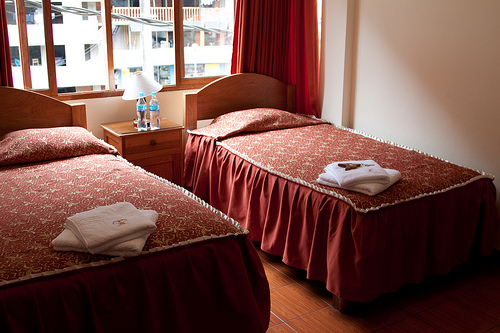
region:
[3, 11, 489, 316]
two beds in hotel room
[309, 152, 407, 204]
folded towels on bed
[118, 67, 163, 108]
tilted white lamp shade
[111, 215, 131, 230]
emblem on white folded towel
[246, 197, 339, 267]
red skirt on bed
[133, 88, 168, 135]
two water bottles on table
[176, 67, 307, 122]
plain wood headboard behind pillow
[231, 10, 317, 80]
open red drapes on side of window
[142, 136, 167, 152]
knob on table drawer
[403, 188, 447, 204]
white trim around bedspread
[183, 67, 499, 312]
There are 2 beds in this room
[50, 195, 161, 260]
There are 2 towels on the bed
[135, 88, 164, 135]
There is 2 bottles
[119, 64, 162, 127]
One Lamp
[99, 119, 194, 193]
One in table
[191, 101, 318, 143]
One pillow on each bed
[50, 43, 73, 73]
Windows are facing building across from the windows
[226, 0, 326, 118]
The room has curtains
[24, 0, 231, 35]
There is 2 cables outside the window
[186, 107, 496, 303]
The blanket is a root beer color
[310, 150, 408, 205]
towels on a bed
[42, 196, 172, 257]
two towels on a bed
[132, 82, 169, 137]
unopened bottles of water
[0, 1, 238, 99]
a large window overlooking a neighbor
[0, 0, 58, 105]
a window that is open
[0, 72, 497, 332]
a pair of twin beds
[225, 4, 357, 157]
a curtain color coordinated with a bedspread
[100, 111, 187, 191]
a small night stand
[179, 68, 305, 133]
a wooden headboard with an arch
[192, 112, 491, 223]
ribbing around the bedspread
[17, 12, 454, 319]
hotel bedroom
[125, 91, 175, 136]
two water bottles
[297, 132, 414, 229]
fancy towels on hotel bed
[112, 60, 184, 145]
lamp behind two waters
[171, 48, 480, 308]
hotel bed with red blankets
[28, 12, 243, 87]
view out hotel window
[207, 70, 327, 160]
red pillow case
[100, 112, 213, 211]
bedroom night stand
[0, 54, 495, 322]
One large and one small hotel bed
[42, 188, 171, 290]
towel with anchor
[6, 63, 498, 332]
Two beds in a room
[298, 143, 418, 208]
White decorated towels on the bed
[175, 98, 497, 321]
Red comforter on bed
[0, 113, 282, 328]
Red comforter on bed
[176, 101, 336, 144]
Pillow is red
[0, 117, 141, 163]
Pillow is red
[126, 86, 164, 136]
Two bottles of water on night table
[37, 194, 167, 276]
Towels are white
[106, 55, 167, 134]
Lamp on the night table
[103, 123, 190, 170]
Night table is brown